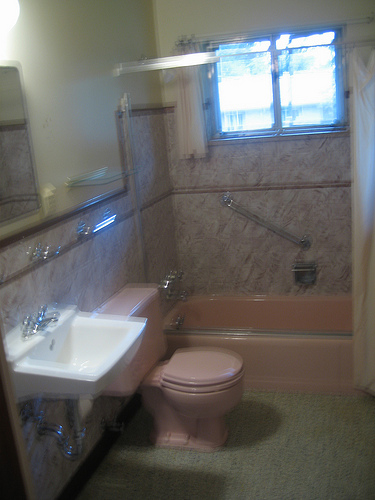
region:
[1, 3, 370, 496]
picture is blurry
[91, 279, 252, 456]
salmon colored toilet bowl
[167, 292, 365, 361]
salmon colored bathtub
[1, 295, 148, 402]
white colored bathroom sink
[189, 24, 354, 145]
window composed of two glass panels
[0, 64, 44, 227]
mirror hanging on wall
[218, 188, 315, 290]
handle bar sideways on wall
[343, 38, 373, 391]
shower curtain partially visible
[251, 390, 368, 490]
floor is dark green colored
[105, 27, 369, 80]
silver shower curtain holder above bathtub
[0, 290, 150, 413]
white sink mounted on the wall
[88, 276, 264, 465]
ceramic toilet colored pink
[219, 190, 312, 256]
silver grab bar mounted on the wall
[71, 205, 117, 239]
silver grab bar mounted on the wall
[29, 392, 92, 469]
silver p trap under the sink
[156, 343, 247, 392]
toilet seat made of plastic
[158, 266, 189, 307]
silver bath tub faucet above tub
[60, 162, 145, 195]
glass shelf mounted on the wall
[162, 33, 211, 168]
white curtain hanging near window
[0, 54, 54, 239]
mirror mounted above the sink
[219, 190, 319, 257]
handicap bar on wall in tub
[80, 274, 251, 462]
toilet bowl between sink and tub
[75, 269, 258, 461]
toilet bowl is pink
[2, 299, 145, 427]
sink under the mirror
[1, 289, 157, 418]
sink on wall is white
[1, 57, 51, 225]
mirror above the sink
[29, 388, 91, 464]
pipe from wall to sink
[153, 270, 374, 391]
tub is pink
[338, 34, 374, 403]
shower curtain in front of tub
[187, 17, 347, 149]
small window above tub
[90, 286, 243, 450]
A pink toilet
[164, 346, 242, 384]
A pink toilet seat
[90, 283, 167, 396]
A pink toilet tank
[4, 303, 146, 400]
A white sink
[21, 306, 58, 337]
A silver faucet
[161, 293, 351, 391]
A pink bath tub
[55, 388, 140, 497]
A back baseboard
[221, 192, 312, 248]
A silver handle in a bath tub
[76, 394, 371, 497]
A light colored bathroom floor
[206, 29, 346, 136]
A rectangle window in a bathroom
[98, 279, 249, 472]
the toilet is pink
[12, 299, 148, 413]
the sink is white